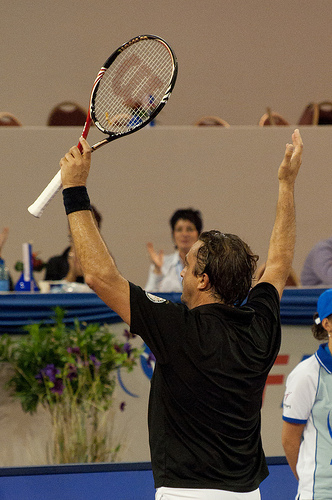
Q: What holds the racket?
A: The man's left hand.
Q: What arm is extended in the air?
A: The right arm.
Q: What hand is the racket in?
A: The left hand.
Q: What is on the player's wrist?
A: A wristband.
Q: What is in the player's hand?
A: A racket.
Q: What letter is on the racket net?
A: W.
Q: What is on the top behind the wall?
A: Chairs.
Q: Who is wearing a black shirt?
A: The tennis player.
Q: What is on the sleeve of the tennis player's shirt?
A: A patch.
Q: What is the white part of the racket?
A: The handle.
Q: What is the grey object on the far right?
A: A person's shirt.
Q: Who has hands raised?
A: Tennis player.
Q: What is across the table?
A: Blue fabric.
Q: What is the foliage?
A: Green and purple plant.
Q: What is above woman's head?
A: Empty chairs.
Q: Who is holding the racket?
A: Tennis player.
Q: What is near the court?
A: Flowers.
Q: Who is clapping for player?
A: Judges.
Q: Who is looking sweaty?
A: Tennis player.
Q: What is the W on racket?
A: Name brand.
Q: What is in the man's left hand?
A: A tennis racquet.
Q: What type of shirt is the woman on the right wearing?
A: A short sleeve shirt.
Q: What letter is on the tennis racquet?
A: A "W".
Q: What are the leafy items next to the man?
A: Flowers.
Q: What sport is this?
A: Tennis.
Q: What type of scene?
A: Outdoor.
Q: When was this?
A: Daytime.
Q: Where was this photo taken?
A: Tennis court.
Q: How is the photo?
A: Clear.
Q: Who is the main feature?
A: A player.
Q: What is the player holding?
A: Racquet.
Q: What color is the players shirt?
A: Black.